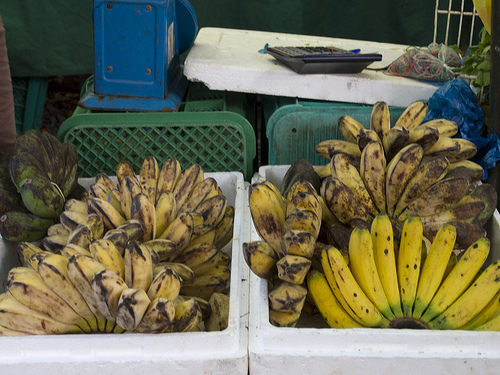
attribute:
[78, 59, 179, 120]
box — BLUE, SITTING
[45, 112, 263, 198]
crate — GREEN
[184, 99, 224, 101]
lids — white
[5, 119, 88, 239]
bananas — green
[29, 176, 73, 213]
banana — green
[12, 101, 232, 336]
bananas — RIPE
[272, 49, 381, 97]
calculator — LARGE, BLACK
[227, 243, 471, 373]
tub — white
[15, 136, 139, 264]
bananas — green, spotty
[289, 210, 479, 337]
bananas — yellow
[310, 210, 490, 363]
bananas — yellow, black, spotted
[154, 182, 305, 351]
tubs — white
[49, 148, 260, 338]
bananas — inside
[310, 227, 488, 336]
bananas — ripe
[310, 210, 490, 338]
bananas — yellow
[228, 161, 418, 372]
box — white, foam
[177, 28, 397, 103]
box — foam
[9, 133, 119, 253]
bananas — green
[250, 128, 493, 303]
bananas — spotted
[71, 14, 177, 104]
box — blue, metal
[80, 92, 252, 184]
crate — square, green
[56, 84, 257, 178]
basket — green, plastic